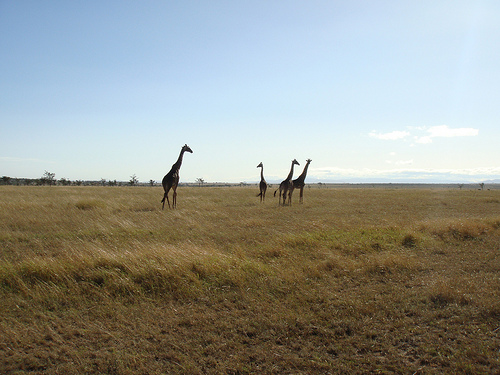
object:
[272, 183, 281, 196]
tail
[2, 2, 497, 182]
sky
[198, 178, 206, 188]
tree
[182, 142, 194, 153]
head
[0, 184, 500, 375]
grass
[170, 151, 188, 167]
neck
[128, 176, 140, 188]
trees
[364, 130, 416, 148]
clouds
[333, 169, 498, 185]
hills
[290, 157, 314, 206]
giraffe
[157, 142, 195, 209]
giraffe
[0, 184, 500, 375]
plain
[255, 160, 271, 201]
giraffe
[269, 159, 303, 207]
giraffe